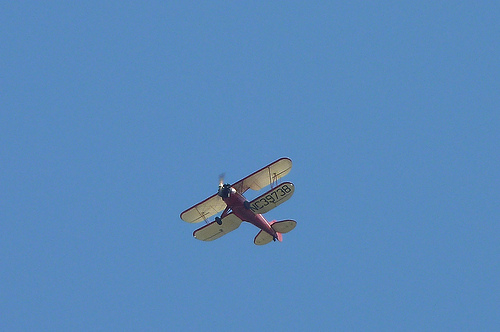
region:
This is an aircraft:
[173, 140, 335, 287]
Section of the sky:
[42, 263, 169, 328]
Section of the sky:
[183, 255, 308, 330]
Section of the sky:
[338, 119, 468, 248]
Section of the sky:
[36, 85, 188, 174]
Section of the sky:
[197, 29, 373, 140]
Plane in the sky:
[159, 158, 316, 265]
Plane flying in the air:
[148, 153, 307, 260]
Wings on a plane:
[225, 155, 305, 215]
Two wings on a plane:
[161, 190, 248, 245]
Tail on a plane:
[255, 220, 310, 250]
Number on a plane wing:
[241, 176, 311, 211]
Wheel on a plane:
[209, 205, 228, 230]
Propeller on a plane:
[207, 168, 243, 203]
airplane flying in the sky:
[180, 155, 298, 248]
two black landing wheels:
[212, 198, 250, 227]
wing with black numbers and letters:
[248, 180, 293, 216]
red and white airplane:
[177, 157, 298, 245]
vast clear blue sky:
[1, 0, 497, 330]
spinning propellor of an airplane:
[211, 167, 231, 198]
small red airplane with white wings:
[177, 153, 295, 246]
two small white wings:
[249, 216, 297, 248]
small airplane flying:
[178, 155, 298, 248]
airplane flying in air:
[179, 156, 298, 246]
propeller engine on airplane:
[213, 174, 229, 201]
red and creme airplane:
[176, 155, 298, 249]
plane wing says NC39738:
[243, 184, 295, 214]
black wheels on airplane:
[213, 198, 251, 224]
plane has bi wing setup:
[178, 156, 294, 241]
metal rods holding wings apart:
[195, 165, 285, 231]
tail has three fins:
[254, 219, 299, 248]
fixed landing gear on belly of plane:
[213, 197, 279, 244]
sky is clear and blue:
[0, 0, 499, 330]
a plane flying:
[177, 153, 306, 253]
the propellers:
[212, 168, 229, 189]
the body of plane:
[219, 183, 282, 248]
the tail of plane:
[253, 214, 299, 248]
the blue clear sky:
[2, 4, 499, 329]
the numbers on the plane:
[256, 186, 296, 206]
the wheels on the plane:
[210, 200, 258, 232]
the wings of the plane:
[177, 157, 301, 248]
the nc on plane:
[251, 199, 264, 213]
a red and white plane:
[181, 153, 313, 250]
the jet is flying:
[177, 136, 311, 266]